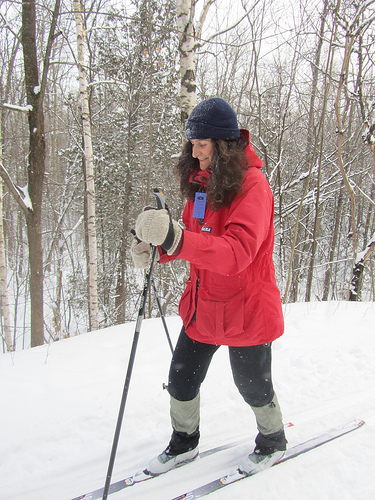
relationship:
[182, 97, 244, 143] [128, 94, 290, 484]
hat worn by woman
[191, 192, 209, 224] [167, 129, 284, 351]
tag on coat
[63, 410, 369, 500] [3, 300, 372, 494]
skis in snow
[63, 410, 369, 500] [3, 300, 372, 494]
skis on snow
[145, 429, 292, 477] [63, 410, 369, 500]
boots on skis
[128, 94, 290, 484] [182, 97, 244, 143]
woman wearing hat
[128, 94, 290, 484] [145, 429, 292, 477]
woman has boots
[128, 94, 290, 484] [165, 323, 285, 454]
woman wears pants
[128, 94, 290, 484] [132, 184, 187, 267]
woman has gloves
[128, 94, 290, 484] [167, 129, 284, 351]
woman wears coat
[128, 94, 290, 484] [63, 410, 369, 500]
woman on skis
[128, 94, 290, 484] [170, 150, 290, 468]
woman wearing clothes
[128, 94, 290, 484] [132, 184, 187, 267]
woman wears gloves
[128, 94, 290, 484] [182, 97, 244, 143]
woman wears hat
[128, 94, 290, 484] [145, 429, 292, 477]
woman wears boots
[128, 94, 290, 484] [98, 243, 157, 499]
woman holds pole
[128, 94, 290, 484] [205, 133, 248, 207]
woman has long hair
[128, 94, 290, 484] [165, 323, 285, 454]
woman wearing pants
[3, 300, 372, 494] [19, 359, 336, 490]
snow on ground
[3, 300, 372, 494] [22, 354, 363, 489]
snow on slopes